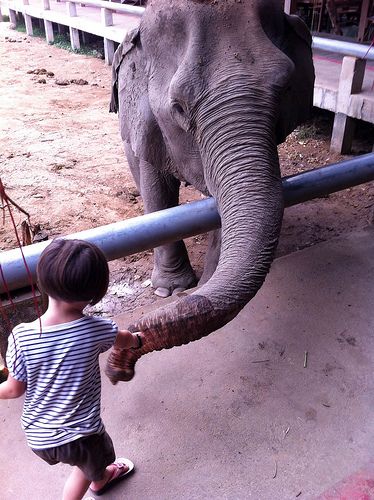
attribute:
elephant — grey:
[113, 1, 313, 385]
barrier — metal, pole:
[5, 152, 362, 300]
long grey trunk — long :
[102, 98, 299, 377]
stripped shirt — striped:
[1, 316, 157, 443]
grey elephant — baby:
[73, 41, 330, 193]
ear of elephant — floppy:
[272, 8, 347, 144]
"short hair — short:
[23, 234, 121, 290]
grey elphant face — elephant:
[115, 1, 308, 135]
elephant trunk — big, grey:
[182, 144, 322, 325]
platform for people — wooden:
[263, 16, 369, 132]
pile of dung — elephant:
[23, 61, 95, 108]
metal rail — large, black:
[75, 201, 205, 263]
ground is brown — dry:
[48, 134, 263, 311]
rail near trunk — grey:
[104, 3, 147, 24]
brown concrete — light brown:
[181, 358, 345, 455]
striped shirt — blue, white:
[13, 343, 118, 439]